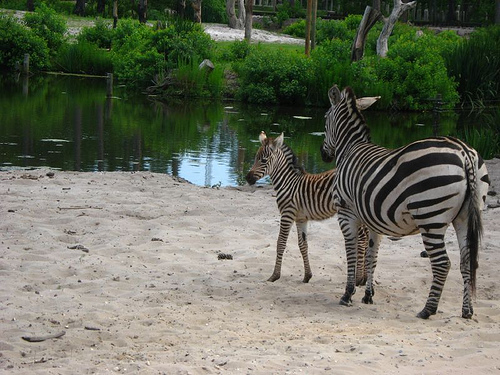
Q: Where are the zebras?
A: Next to the water.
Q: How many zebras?
A: 2.